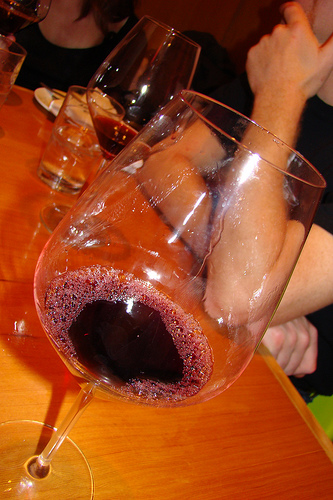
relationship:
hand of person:
[233, 15, 325, 102] [110, 0, 318, 427]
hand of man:
[233, 15, 325, 102] [110, 0, 318, 427]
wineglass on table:
[48, 4, 215, 248] [23, 96, 264, 471]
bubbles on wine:
[130, 374, 199, 400] [41, 247, 240, 410]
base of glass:
[8, 395, 118, 500] [20, 79, 330, 350]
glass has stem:
[20, 79, 330, 350] [16, 355, 134, 478]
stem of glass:
[16, 355, 134, 478] [20, 79, 330, 350]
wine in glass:
[41, 247, 240, 410] [20, 79, 330, 350]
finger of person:
[271, 4, 319, 27] [110, 0, 318, 427]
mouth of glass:
[174, 70, 327, 199] [20, 79, 330, 350]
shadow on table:
[6, 268, 86, 408] [23, 96, 264, 471]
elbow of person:
[191, 234, 256, 347] [110, 0, 318, 427]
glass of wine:
[20, 79, 330, 350] [41, 247, 240, 410]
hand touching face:
[233, 15, 325, 102] [284, 9, 331, 89]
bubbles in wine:
[130, 374, 199, 400] [41, 247, 240, 410]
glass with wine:
[20, 79, 330, 350] [41, 247, 240, 410]